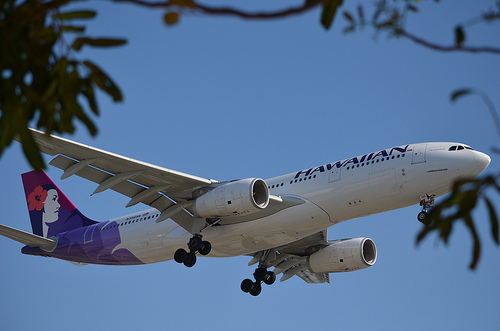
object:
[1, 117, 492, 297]
plane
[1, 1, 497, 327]
sky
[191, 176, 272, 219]
right engine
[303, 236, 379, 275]
left engine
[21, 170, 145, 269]
graphic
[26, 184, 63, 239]
woman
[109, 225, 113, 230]
rear windows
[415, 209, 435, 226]
front wheels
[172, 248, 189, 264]
rear right wheels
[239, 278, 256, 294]
rear left wheels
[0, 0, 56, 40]
leaves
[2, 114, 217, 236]
right wing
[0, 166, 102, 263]
tail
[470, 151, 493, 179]
nose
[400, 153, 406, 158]
front windows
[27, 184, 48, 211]
flower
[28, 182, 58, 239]
hair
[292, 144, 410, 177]
writing